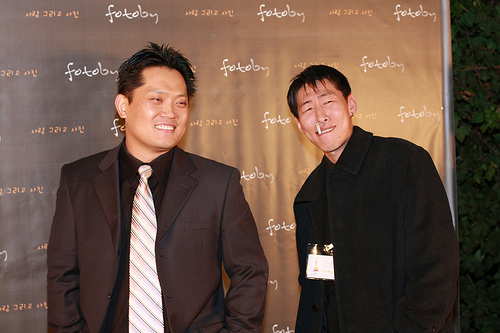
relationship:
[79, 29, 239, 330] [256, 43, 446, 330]
man beside man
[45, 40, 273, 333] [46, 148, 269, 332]
man wearing jacket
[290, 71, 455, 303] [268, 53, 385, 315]
coat on man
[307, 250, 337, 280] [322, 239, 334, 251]
card with clip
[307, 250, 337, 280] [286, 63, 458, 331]
card on man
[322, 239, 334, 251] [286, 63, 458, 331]
clip on man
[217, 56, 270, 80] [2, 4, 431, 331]
lettering on backdrop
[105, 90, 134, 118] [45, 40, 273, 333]
ear of man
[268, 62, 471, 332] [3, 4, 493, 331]
man standing outside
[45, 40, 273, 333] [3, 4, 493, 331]
man standing outside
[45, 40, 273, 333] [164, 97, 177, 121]
man has nose